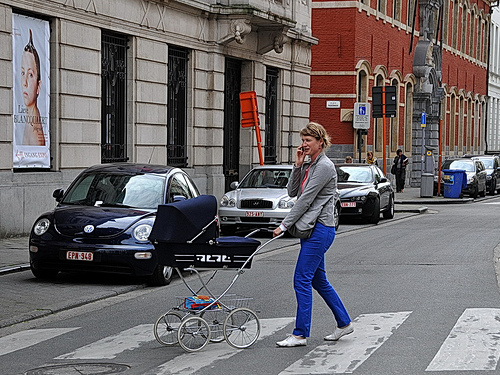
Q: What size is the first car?
A: Small.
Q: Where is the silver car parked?
A: Between 2 cars next to the curb.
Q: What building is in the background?
A: A red brick building.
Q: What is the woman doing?
A: Pushing a stroller.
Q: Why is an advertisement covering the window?
A: To inform people about an exhibit.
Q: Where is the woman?
A: On a city street.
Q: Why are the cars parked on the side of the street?
A: The area is designated for parking.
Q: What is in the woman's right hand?
A: A cellphone.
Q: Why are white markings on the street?
A: It is crosswalk.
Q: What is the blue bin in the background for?
A: Garbage.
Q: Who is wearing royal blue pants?
A: Woman pushing the stroller.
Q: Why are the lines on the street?
A: To show people where to cross.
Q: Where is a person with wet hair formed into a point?
A: In an advertisement on the wall.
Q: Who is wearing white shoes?
A: Woman pushing the stroller.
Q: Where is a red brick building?
A: In the background to the right.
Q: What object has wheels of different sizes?
A: The stroller.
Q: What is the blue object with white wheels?
A: Baby stroller.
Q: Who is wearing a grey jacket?
A: Woman pushing the stroller.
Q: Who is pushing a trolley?
A: A woman.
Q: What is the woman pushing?
A: Trolley.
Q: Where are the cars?
A: Side street.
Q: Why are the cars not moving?
A: Parked.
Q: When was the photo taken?
A: Daylight.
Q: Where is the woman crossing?
A: Cross level.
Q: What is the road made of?
A: Tarmac.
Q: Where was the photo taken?
A: Street.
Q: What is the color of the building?
A: Grey and red.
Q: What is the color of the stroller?
A: Blue.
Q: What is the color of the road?
A: Grey.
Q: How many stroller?
A: 1.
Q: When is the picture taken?
A: Daytime.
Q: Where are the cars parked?
A: On the road side.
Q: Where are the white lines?
A: In the road.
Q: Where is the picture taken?
A: At a crosswalk.